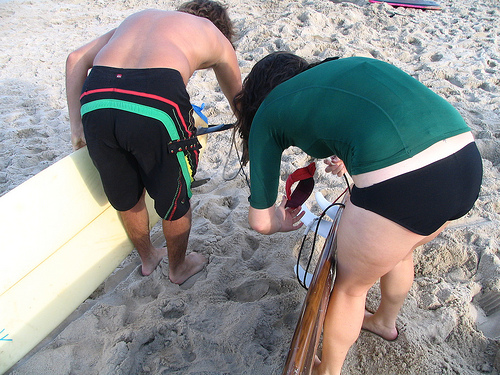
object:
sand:
[2, 0, 499, 375]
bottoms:
[350, 140, 484, 236]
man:
[63, 2, 248, 285]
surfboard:
[1, 112, 208, 373]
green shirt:
[241, 51, 471, 210]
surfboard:
[284, 184, 354, 374]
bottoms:
[80, 65, 203, 222]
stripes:
[80, 99, 194, 199]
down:
[230, 51, 346, 169]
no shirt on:
[66, 9, 241, 150]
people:
[229, 50, 483, 374]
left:
[2, 5, 56, 371]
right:
[478, 1, 500, 373]